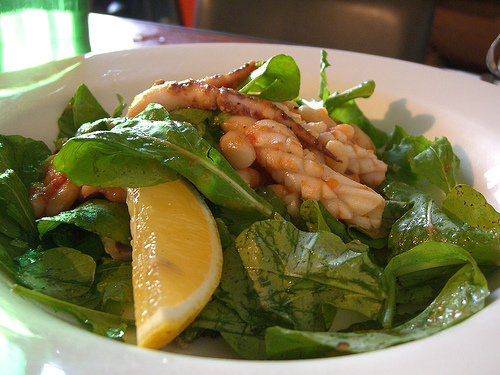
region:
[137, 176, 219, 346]
there is a lemon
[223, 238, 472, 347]
greens are on the plate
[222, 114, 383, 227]
meat is in the salad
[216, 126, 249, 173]
beans are with the salad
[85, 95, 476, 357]
this is a salad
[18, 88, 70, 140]
dish is white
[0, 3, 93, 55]
glass is next to salad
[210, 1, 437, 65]
there is a chair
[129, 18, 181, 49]
utensils by the plate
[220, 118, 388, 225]
dressing on the salad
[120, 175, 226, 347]
A juicy, yellow lemon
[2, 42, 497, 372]
A salad in a white dish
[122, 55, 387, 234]
Meat on top of a salad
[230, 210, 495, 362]
Green leaves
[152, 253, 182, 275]
A seed in a lemon slice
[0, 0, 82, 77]
Green light reflected off table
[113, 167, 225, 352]
A sliced citrus fruit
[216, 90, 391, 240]
Seafood on top of spinach leaves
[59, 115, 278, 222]
A spinach leaf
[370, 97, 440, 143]
The shadow of a spinach leaf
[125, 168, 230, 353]
a yellow lemon in the salad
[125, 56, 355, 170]
a piece of chicken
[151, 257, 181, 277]
a seed in the lemon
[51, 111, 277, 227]
a leaf of green spinach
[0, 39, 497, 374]
a white salad bowl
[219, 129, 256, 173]
a brown bean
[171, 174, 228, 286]
the rind of the lemon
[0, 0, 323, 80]
a table under the bowl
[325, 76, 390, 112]
the stem of a spinach leaf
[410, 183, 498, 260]
dressing on the leaf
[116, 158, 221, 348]
yellow lemon wedge on salad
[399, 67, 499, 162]
white bowl holding salad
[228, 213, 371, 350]
green leaf vegetable under meat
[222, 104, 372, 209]
cooked meat on salad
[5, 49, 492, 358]
salad at a resaurant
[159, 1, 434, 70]
empty grey chair across table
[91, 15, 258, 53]
restaurant table behind plate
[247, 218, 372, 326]
lettuce has dark green marks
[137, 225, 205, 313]
lemon wedge has seeds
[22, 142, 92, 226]
some type of tomato sauce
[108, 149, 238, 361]
Thin lemon wedge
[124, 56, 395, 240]
Lightly grilled fish slice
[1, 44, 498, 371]
Large flat bowl of fish and greens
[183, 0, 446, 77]
Brown padded chair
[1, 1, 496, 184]
Brown table reflecting light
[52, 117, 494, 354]
Bed of wet green leafy vegetables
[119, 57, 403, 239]
Lightly grilled pieces of sliced fish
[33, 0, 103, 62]
Green drinking glass reflecting light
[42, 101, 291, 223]
Spinach leaf resting on thin lemon slice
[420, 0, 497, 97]
Small brown chair